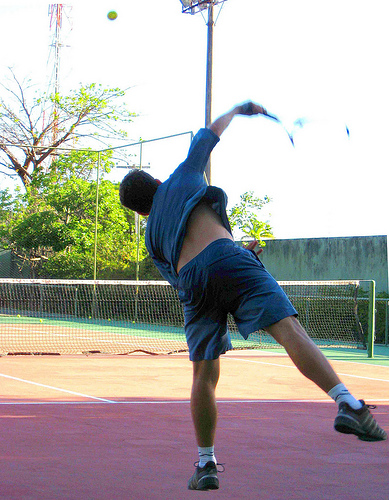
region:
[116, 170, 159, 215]
Black hair on the back of a man's head.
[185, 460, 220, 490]
A black and silver shoe with red stripes on a man's left foot.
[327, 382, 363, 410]
Mostly white sock on a man's right foot.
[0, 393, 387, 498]
Shadow over this half of the court making it look red.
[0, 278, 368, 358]
White and black tennis net.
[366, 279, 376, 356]
Green metal pole holding a tennis net.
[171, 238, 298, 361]
Blue shorts on a man in the air.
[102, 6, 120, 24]
A round tennis ball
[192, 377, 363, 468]
A pair of white socks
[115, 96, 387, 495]
A man swinging a racket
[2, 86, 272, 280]
Green leaves on trees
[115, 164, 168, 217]
Man has dark hair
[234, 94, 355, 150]
Tennis racket in a hand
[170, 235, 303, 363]
A pair of shorts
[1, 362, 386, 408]
White lines on tennis court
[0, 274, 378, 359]
A net on the tennis court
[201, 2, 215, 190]
A tall brown pole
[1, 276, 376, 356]
net on tennis court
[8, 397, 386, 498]
large purple shadow on court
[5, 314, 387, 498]
a green tennis court with white lines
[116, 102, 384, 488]
a man serving a tennis ball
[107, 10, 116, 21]
yellow tennis ball in the air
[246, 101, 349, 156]
a tennis racket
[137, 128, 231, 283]
the tennis player's blue shirt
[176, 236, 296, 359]
the tennis players blue shorts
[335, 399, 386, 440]
the player's right tennis shoe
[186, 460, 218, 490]
the player's left shoe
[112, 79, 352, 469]
man wearing blue shirt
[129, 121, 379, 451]
man wearing blue shorts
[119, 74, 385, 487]
man wearing white socks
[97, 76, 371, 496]
man holding a racket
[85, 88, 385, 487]
man hitting tennis racket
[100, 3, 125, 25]
ball in the air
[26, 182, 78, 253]
trees near a tennis court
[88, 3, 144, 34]
tennis ball high in the air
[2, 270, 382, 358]
tennis net stretched across the court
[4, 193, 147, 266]
green tree on the side of the fence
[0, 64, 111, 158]
tree in the background with bare branches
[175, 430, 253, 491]
Tennis shoe and trimmed white sock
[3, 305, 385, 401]
Tennis court with line markings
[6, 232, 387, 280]
high concert fence surrounding the tennis court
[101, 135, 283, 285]
man's shirt pulled up showing his back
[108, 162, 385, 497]
tennis player standing on one foot, lifting the other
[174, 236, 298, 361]
shorts on man's body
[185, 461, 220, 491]
tennis shoe on man's foot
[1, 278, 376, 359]
tennis net separating court